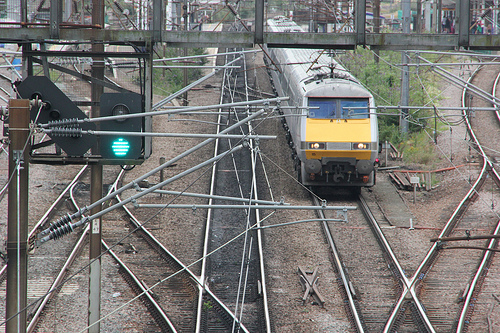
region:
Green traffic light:
[110, 135, 140, 161]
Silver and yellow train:
[270, 40, 381, 189]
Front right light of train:
[307, 137, 328, 150]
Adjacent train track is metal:
[216, 65, 265, 301]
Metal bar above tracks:
[9, 11, 496, 62]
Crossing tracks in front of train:
[336, 254, 479, 331]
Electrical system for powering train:
[95, 79, 336, 236]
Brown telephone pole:
[14, 96, 29, 330]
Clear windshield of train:
[308, 86, 370, 122]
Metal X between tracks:
[290, 249, 325, 314]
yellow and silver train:
[261, 12, 381, 197]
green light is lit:
[110, 137, 130, 155]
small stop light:
[100, 95, 141, 160]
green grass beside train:
[348, 41, 438, 164]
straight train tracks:
[188, 48, 273, 326]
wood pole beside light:
[6, 97, 28, 332]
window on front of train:
[307, 97, 370, 119]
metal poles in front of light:
[23, 87, 290, 235]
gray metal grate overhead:
[0, 0, 499, 51]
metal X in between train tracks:
[292, 259, 329, 308]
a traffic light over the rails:
[83, 85, 159, 175]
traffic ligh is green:
[90, 86, 150, 166]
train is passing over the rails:
[256, 13, 388, 204]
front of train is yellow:
[300, 90, 378, 188]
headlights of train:
[299, 131, 377, 153]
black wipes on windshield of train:
[319, 99, 356, 128]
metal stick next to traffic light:
[159, 48, 322, 259]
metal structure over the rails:
[1, 5, 498, 65]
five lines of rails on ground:
[29, 181, 499, 321]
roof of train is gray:
[279, 49, 370, 103]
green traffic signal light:
[102, 136, 134, 158]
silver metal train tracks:
[337, 246, 402, 291]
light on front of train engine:
[304, 136, 331, 154]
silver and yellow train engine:
[259, 16, 384, 201]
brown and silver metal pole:
[84, 236, 104, 323]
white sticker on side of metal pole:
[90, 213, 102, 236]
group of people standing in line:
[435, 10, 460, 33]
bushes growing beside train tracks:
[366, 67, 396, 89]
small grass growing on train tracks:
[198, 295, 214, 312]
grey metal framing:
[261, 28, 354, 49]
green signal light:
[98, 136, 140, 163]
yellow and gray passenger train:
[272, 54, 379, 196]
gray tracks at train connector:
[99, 213, 201, 323]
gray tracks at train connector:
[217, 72, 273, 321]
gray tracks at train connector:
[312, 210, 424, 317]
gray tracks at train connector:
[423, 135, 493, 320]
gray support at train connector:
[366, 15, 490, 66]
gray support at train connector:
[166, 7, 366, 60]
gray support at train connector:
[11, 10, 156, 58]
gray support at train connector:
[3, 157, 50, 327]